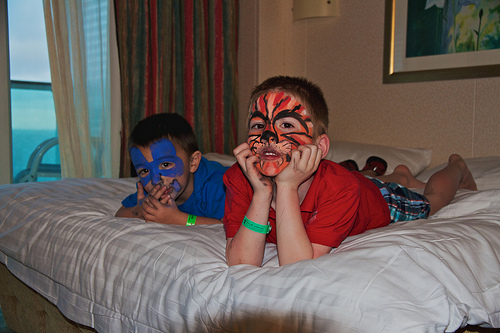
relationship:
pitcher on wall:
[356, 1, 499, 88] [297, 7, 484, 134]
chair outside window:
[14, 117, 105, 184] [6, 0, 111, 183]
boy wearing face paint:
[220, 75, 478, 268] [247, 98, 308, 172]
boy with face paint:
[98, 104, 227, 234] [133, 143, 191, 201]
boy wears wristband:
[206, 79, 490, 287] [184, 206, 201, 232]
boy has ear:
[220, 75, 478, 268] [188, 149, 203, 174]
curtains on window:
[50, 5, 238, 182] [2, 8, 121, 168]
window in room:
[12, 13, 101, 178] [4, 7, 495, 328]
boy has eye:
[220, 75, 478, 268] [278, 120, 303, 130]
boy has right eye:
[220, 75, 478, 268] [252, 120, 264, 130]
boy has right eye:
[220, 75, 478, 268] [137, 164, 149, 175]